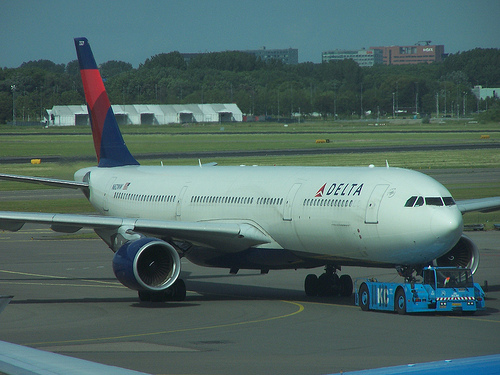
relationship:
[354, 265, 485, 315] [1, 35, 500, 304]
service vehicle underneath airplane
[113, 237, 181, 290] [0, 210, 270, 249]
turbine engine under wing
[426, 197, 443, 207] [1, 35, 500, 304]
window in front of airplane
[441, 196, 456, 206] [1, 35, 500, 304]
window in front of airplane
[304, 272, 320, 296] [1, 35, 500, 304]
wheel under airplane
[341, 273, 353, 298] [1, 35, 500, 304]
wheel under airplane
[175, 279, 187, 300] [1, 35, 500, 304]
wheel under airplane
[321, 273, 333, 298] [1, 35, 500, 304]
wheel under airplane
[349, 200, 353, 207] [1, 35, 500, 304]
window on airplane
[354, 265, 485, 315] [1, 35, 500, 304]
service vehicle in front of airplane